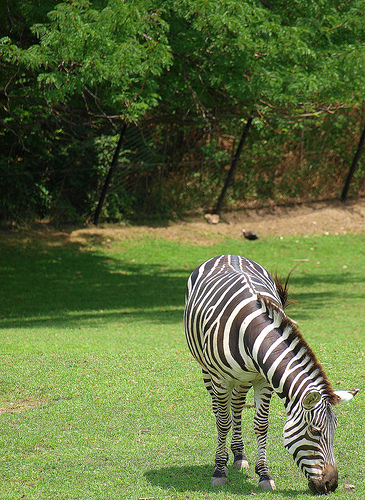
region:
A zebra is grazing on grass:
[181, 254, 356, 494]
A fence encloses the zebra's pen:
[1, 100, 360, 225]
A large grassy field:
[2, 242, 362, 498]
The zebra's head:
[280, 387, 359, 495]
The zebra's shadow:
[143, 460, 310, 494]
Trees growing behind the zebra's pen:
[1, 0, 364, 228]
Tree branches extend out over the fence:
[0, 1, 361, 123]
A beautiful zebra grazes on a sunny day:
[184, 254, 359, 498]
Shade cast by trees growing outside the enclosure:
[0, 231, 364, 313]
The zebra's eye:
[305, 421, 324, 439]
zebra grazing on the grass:
[179, 245, 350, 495]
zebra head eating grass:
[279, 377, 355, 490]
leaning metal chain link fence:
[62, 108, 334, 244]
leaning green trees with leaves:
[16, 18, 285, 137]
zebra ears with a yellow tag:
[302, 381, 357, 419]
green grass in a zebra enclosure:
[38, 294, 138, 443]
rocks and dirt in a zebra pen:
[149, 199, 295, 256]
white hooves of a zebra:
[205, 454, 292, 489]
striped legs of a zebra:
[204, 379, 274, 472]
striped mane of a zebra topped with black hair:
[260, 294, 350, 388]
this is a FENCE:
[122, 126, 232, 196]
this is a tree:
[73, 8, 151, 97]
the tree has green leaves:
[120, 56, 138, 77]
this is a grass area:
[48, 274, 136, 377]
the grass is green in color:
[93, 359, 132, 426]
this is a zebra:
[198, 253, 352, 496]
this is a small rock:
[206, 210, 218, 226]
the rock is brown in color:
[208, 212, 215, 221]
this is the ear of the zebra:
[301, 392, 318, 410]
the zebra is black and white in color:
[214, 302, 242, 356]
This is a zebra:
[199, 259, 355, 496]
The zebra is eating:
[247, 412, 364, 494]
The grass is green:
[66, 340, 186, 469]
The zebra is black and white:
[206, 285, 275, 418]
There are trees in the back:
[93, 64, 330, 133]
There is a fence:
[82, 113, 360, 245]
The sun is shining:
[52, 359, 179, 497]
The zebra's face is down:
[294, 420, 337, 491]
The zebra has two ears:
[291, 372, 361, 424]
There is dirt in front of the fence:
[240, 210, 361, 288]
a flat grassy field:
[5, 402, 195, 488]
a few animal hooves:
[197, 454, 292, 492]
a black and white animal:
[161, 234, 350, 490]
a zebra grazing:
[165, 237, 360, 497]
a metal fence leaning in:
[29, 123, 318, 230]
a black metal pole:
[223, 105, 257, 244]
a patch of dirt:
[245, 200, 349, 244]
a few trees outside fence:
[9, 2, 347, 143]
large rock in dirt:
[190, 198, 242, 242]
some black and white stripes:
[200, 382, 235, 441]